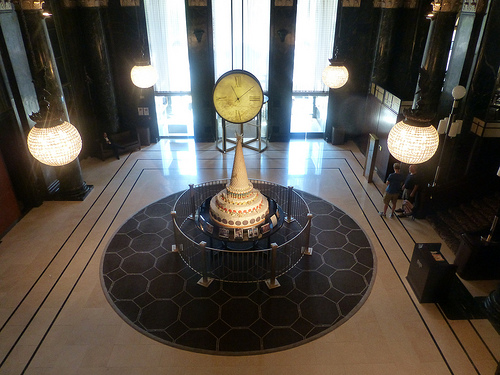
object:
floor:
[1, 135, 500, 374]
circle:
[98, 179, 378, 358]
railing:
[168, 176, 314, 283]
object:
[198, 133, 281, 242]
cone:
[227, 131, 252, 189]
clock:
[212, 70, 267, 124]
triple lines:
[0, 150, 133, 332]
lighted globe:
[24, 124, 87, 165]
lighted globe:
[127, 67, 161, 89]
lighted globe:
[320, 58, 349, 91]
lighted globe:
[387, 114, 440, 164]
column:
[14, 2, 95, 202]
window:
[153, 91, 191, 137]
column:
[386, 2, 463, 198]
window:
[289, 0, 339, 92]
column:
[370, 4, 394, 98]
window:
[211, 0, 269, 93]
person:
[380, 161, 404, 218]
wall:
[464, 246, 500, 280]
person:
[395, 165, 419, 220]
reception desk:
[406, 241, 456, 304]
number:
[233, 73, 244, 87]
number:
[248, 94, 262, 102]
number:
[233, 108, 244, 122]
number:
[216, 92, 230, 103]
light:
[451, 87, 467, 99]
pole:
[433, 84, 468, 186]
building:
[1, 1, 500, 373]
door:
[1, 146, 26, 233]